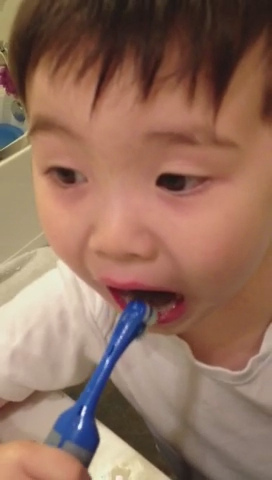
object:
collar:
[172, 314, 272, 382]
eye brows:
[145, 119, 246, 151]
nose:
[87, 200, 157, 261]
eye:
[153, 146, 215, 201]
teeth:
[107, 272, 180, 325]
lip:
[100, 277, 175, 291]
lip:
[108, 297, 189, 326]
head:
[6, 1, 270, 336]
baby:
[0, 0, 272, 478]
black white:
[153, 173, 207, 194]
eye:
[39, 159, 90, 190]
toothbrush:
[42, 298, 156, 465]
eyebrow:
[27, 115, 82, 144]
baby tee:
[0, 246, 272, 480]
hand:
[0, 431, 102, 479]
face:
[26, 73, 252, 350]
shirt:
[0, 254, 270, 480]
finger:
[18, 438, 97, 478]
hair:
[3, 0, 271, 144]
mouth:
[102, 274, 187, 324]